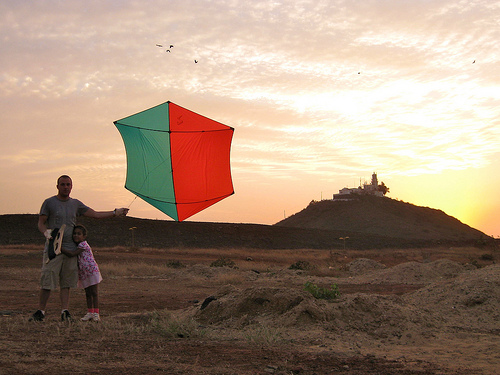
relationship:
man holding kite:
[27, 170, 135, 321] [106, 90, 241, 225]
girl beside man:
[58, 223, 107, 325] [27, 170, 135, 321]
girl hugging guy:
[68, 220, 115, 310] [9, 156, 98, 306]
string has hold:
[57, 191, 139, 241] [46, 222, 66, 264]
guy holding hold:
[27, 173, 129, 324] [46, 222, 66, 264]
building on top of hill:
[332, 170, 387, 197] [271, 195, 488, 241]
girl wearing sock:
[68, 220, 115, 310] [91, 306, 99, 313]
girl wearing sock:
[68, 220, 115, 310] [85, 306, 92, 313]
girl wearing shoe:
[68, 220, 115, 310] [91, 313, 101, 323]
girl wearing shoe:
[68, 220, 115, 310] [80, 310, 92, 322]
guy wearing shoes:
[27, 173, 129, 324] [22, 312, 75, 324]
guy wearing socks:
[27, 173, 129, 324] [39, 309, 69, 313]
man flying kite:
[27, 170, 131, 321] [105, 97, 247, 222]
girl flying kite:
[68, 220, 115, 310] [105, 97, 247, 222]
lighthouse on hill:
[367, 171, 381, 186] [271, 195, 488, 241]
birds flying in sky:
[151, 38, 201, 71] [7, 9, 482, 237]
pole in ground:
[123, 223, 140, 249] [2, 241, 499, 373]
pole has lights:
[123, 223, 140, 249] [129, 223, 135, 227]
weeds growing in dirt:
[214, 235, 465, 324] [251, 286, 459, 371]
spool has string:
[47, 221, 74, 261] [46, 222, 59, 263]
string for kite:
[46, 222, 59, 263] [106, 90, 241, 225]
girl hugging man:
[68, 220, 115, 310] [27, 170, 131, 321]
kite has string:
[109, 95, 249, 232] [119, 189, 134, 210]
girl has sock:
[68, 220, 115, 310] [92, 305, 100, 315]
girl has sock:
[68, 220, 115, 310] [84, 304, 94, 314]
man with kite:
[27, 170, 131, 321] [109, 95, 249, 232]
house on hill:
[334, 169, 394, 206] [314, 201, 444, 250]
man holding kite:
[27, 170, 131, 321] [112, 99, 239, 225]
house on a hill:
[331, 169, 392, 199] [274, 192, 496, 244]